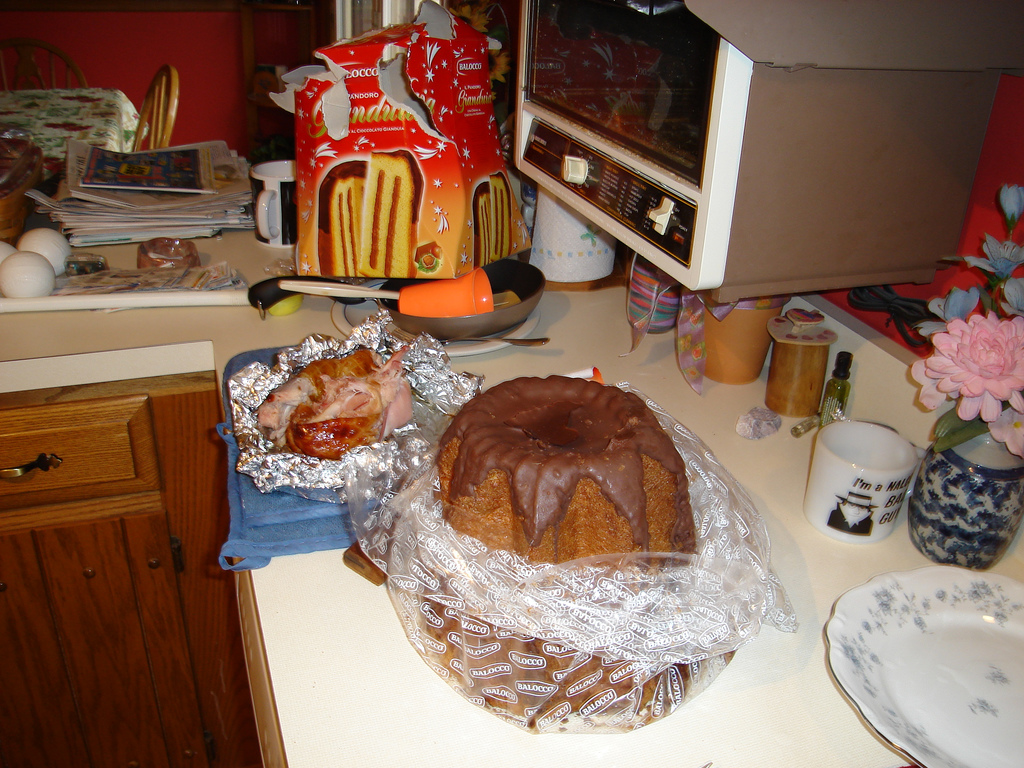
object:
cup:
[395, 263, 497, 320]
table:
[0, 86, 145, 164]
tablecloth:
[0, 80, 150, 154]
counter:
[3, 365, 242, 768]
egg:
[0, 253, 54, 301]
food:
[435, 372, 692, 579]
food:
[232, 337, 440, 463]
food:
[0, 197, 69, 329]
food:
[131, 234, 203, 290]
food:
[291, 9, 523, 277]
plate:
[822, 564, 1020, 753]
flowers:
[901, 308, 1024, 427]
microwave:
[515, 0, 1007, 319]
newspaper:
[27, 143, 255, 251]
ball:
[2, 246, 57, 299]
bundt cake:
[411, 375, 743, 676]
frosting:
[441, 376, 684, 480]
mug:
[800, 418, 921, 547]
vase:
[904, 430, 1024, 582]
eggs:
[13, 223, 68, 276]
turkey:
[243, 356, 410, 456]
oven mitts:
[211, 314, 427, 585]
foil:
[214, 451, 430, 499]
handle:
[2, 445, 63, 483]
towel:
[228, 500, 389, 572]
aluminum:
[227, 445, 437, 499]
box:
[287, 5, 531, 283]